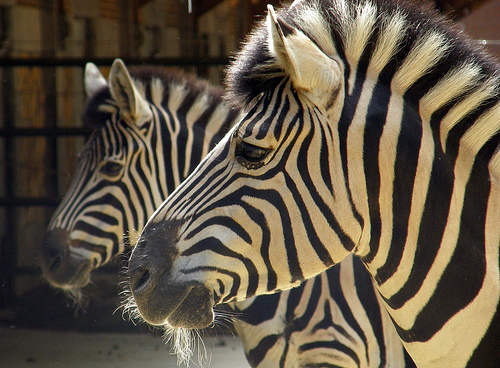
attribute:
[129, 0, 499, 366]
zebra — striped, black, white, patterned, wild, furry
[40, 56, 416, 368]
zebra — striped, black, white, patterned, wild, furry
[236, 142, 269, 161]
eye — black, large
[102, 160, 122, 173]
eye — black, large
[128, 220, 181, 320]
nose — brown, black, soft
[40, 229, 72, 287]
nose — brown, black, soft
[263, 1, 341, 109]
ear — white, furry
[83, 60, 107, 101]
ear — white, furry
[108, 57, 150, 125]
ear — white, furry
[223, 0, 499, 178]
mane — trimmed, black, white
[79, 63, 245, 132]
mane — trimmed, black, white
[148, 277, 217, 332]
mouth — closed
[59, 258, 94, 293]
mouth — closed